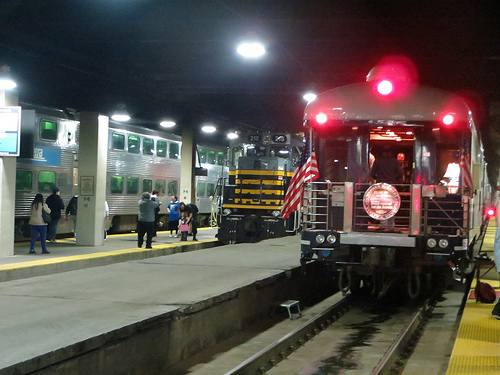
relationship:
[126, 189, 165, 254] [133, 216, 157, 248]
man wearing pants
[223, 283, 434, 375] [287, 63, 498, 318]
rails near platform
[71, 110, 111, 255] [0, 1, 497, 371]
pillar of station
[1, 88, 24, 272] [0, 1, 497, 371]
pillar of station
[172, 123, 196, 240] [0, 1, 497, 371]
pillar of station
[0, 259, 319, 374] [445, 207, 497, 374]
edge of platform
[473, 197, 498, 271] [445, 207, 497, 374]
edge of platform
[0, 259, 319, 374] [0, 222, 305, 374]
edge of platform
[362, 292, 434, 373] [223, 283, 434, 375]
rails of rails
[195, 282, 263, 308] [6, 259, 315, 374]
part of edge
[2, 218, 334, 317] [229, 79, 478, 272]
platform near train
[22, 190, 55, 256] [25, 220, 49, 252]
woman wearing blue jeans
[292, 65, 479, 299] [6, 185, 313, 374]
train in platform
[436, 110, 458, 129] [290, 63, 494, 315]
headlights in train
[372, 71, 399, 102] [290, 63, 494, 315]
headlights in train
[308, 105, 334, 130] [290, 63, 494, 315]
headlights in train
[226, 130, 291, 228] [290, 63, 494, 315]
train near by train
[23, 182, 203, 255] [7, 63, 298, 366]
passengers walking in railway station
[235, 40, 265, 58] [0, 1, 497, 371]
light in station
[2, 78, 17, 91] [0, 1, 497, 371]
light in station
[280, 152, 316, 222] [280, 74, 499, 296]
flag flying on train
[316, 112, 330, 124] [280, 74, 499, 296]
headlights on train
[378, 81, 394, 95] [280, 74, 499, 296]
headlights on train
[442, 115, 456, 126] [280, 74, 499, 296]
headlights on train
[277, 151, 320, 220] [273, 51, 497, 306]
flag on train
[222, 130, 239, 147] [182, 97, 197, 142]
light on ceiling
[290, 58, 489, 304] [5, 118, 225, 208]
train with levels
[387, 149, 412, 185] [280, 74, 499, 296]
person inside train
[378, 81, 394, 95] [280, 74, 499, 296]
headlights on a train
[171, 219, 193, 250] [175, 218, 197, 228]
child wearing pink shirt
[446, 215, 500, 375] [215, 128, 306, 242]
yellow paint on front of train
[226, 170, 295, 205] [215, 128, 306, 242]
black paint on front of train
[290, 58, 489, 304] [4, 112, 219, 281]
train stopped train station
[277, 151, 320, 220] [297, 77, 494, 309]
flag on back of train